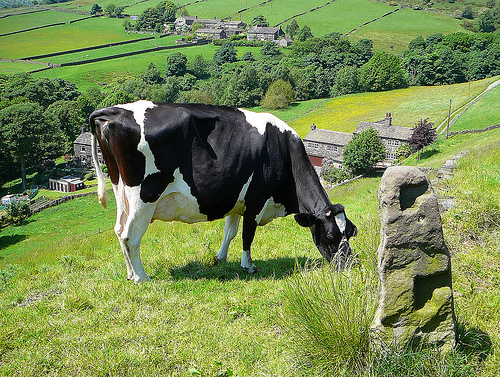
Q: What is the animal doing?
A: Eating.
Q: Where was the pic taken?
A: In the field.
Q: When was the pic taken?
A: During the day.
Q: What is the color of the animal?
A: Black and white.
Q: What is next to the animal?
A: Rock.